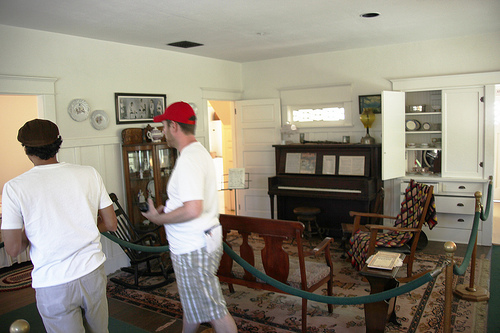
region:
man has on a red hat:
[157, 103, 200, 118]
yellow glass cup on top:
[360, 117, 372, 138]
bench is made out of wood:
[271, 241, 276, 265]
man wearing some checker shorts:
[185, 254, 208, 316]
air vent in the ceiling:
[167, 40, 199, 53]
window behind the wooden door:
[286, 99, 347, 125]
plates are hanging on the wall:
[72, 97, 105, 129]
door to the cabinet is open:
[383, 96, 400, 177]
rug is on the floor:
[2, 261, 29, 293]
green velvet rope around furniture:
[288, 185, 497, 327]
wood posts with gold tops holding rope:
[426, 225, 467, 330]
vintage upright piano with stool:
[268, 109, 389, 243]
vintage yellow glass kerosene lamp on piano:
[353, 102, 381, 153]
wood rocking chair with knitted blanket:
[333, 172, 435, 291]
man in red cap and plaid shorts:
[138, 92, 245, 331]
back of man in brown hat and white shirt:
[5, 111, 127, 330]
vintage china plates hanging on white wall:
[65, 91, 116, 132]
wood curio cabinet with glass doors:
[119, 118, 202, 279]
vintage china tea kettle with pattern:
[139, 119, 169, 148]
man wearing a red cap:
[151, 99, 196, 126]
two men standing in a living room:
[2, 99, 239, 331]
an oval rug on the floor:
[0, 262, 35, 287]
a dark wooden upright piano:
[266, 142, 378, 239]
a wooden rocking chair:
[348, 178, 431, 285]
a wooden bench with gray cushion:
[217, 215, 337, 329]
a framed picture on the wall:
[113, 92, 168, 124]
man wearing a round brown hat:
[19, 117, 59, 150]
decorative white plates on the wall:
[67, 96, 111, 131]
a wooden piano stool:
[293, 205, 326, 244]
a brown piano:
[234, 110, 399, 235]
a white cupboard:
[356, 79, 496, 236]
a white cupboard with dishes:
[347, 52, 498, 264]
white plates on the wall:
[52, 98, 135, 155]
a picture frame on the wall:
[103, 78, 213, 150]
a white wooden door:
[220, 85, 295, 260]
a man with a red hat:
[120, 85, 212, 178]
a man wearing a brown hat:
[11, 108, 88, 195]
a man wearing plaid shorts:
[131, 105, 236, 318]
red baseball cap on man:
[157, 108, 192, 124]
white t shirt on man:
[1, 184, 111, 305]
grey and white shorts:
[169, 263, 275, 311]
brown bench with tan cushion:
[242, 207, 349, 322]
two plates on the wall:
[83, 93, 118, 150]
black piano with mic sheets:
[274, 116, 370, 221]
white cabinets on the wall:
[392, 62, 497, 207]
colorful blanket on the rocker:
[347, 186, 448, 294]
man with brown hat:
[24, 111, 77, 166]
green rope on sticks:
[234, 230, 496, 288]